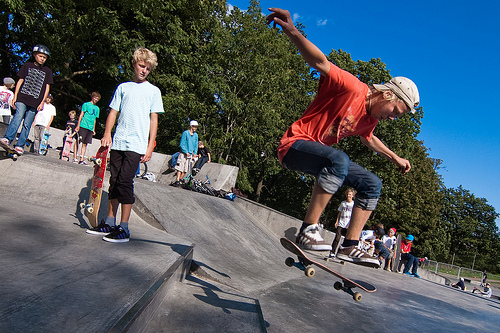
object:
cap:
[372, 76, 420, 114]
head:
[370, 76, 419, 121]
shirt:
[79, 101, 100, 131]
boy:
[85, 50, 164, 243]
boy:
[176, 120, 198, 181]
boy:
[0, 45, 54, 156]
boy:
[266, 8, 421, 268]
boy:
[31, 94, 56, 154]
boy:
[0, 78, 15, 129]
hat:
[190, 120, 199, 126]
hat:
[4, 77, 15, 83]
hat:
[32, 44, 50, 56]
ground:
[0, 150, 500, 333]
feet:
[296, 229, 332, 251]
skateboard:
[279, 238, 377, 302]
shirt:
[277, 61, 379, 164]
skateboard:
[79, 147, 109, 230]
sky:
[249, 0, 500, 198]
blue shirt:
[109, 81, 165, 155]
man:
[401, 234, 423, 279]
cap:
[406, 234, 414, 240]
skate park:
[0, 0, 494, 331]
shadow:
[0, 210, 273, 333]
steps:
[165, 237, 269, 331]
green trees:
[0, 0, 497, 274]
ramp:
[133, 178, 300, 294]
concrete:
[0, 300, 500, 333]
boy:
[72, 91, 100, 166]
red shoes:
[2, 138, 9, 146]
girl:
[0, 45, 53, 156]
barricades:
[417, 257, 498, 286]